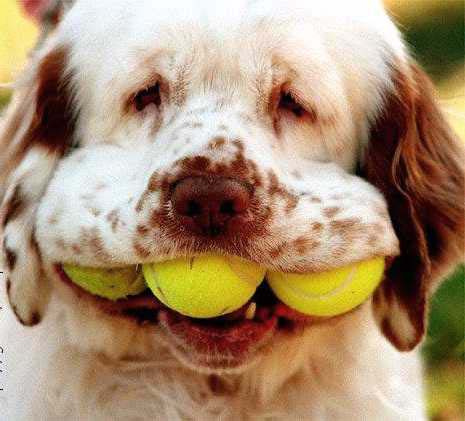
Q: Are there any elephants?
A: No, there are no elephants.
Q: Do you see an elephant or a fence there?
A: No, there are no elephants or fences.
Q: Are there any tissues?
A: No, there are no tissues.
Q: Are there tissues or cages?
A: No, there are no tissues or cages.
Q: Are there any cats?
A: No, there are no cats.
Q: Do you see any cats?
A: No, there are no cats.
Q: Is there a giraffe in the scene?
A: No, there are no giraffes.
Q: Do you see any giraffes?
A: No, there are no giraffes.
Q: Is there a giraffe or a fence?
A: No, there are no giraffes or fences.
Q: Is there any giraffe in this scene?
A: No, there are no giraffes.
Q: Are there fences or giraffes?
A: No, there are no giraffes or fences.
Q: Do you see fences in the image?
A: No, there are no fences.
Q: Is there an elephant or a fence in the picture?
A: No, there are no fences or elephants.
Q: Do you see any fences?
A: No, there are no fences.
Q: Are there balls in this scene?
A: Yes, there is a ball.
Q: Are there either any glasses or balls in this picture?
A: Yes, there is a ball.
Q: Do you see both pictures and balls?
A: No, there is a ball but no pictures.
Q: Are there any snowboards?
A: No, there are no snowboards.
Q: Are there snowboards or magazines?
A: No, there are no snowboards or magazines.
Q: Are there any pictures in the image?
A: No, there are no pictures.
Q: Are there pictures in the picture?
A: No, there are no pictures.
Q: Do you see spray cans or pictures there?
A: No, there are no pictures or spray cans.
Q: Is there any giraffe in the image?
A: No, there are no giraffes.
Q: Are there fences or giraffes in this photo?
A: No, there are no giraffes or fences.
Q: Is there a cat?
A: No, there are no cats.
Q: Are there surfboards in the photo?
A: No, there are no surfboards.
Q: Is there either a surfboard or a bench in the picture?
A: No, there are no surfboards or benches.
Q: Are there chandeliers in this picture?
A: No, there are no chandeliers.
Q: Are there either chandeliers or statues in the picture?
A: No, there are no chandeliers or statues.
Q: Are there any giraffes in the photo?
A: No, there are no giraffes.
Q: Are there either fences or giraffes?
A: No, there are no giraffes or fences.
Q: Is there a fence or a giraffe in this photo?
A: No, there are no giraffes or fences.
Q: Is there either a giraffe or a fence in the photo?
A: No, there are no giraffes or fences.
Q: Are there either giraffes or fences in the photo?
A: No, there are no giraffes or fences.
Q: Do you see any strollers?
A: No, there are no strollers.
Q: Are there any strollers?
A: No, there are no strollers.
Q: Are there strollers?
A: No, there are no strollers.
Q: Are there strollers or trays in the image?
A: No, there are no strollers or trays.